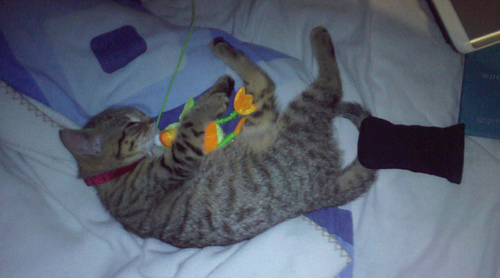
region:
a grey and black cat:
[56, 28, 403, 240]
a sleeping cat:
[47, 39, 424, 240]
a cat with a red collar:
[29, 80, 189, 205]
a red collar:
[64, 143, 156, 201]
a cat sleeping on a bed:
[18, 35, 409, 255]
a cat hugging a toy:
[89, 28, 419, 238]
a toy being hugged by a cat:
[158, 71, 267, 153]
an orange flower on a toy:
[193, 73, 265, 154]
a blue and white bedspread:
[6, 28, 167, 120]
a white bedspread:
[6, 81, 56, 207]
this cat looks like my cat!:
[54, 32, 391, 272]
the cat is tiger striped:
[59, 16, 404, 243]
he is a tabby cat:
[51, 19, 401, 257]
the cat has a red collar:
[54, 15, 423, 262]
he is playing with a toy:
[78, 85, 274, 237]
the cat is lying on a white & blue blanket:
[30, 47, 405, 252]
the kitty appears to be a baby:
[56, 10, 409, 249]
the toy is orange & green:
[147, 49, 284, 161]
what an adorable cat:
[28, 5, 450, 260]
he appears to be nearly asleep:
[47, 12, 415, 263]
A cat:
[123, 43, 317, 275]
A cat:
[127, 106, 226, 174]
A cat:
[185, 84, 268, 220]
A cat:
[141, 132, 265, 237]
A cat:
[187, 58, 254, 141]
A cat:
[198, 179, 308, 271]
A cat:
[179, 136, 295, 255]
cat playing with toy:
[34, 74, 334, 216]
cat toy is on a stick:
[100, 26, 275, 163]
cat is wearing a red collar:
[77, 140, 167, 196]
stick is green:
[170, 20, 194, 114]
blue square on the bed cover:
[84, 23, 154, 70]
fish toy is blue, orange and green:
[159, 98, 266, 150]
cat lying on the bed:
[55, 79, 405, 270]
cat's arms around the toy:
[158, 58, 228, 171]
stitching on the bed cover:
[1, 91, 66, 131]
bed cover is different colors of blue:
[40, 5, 185, 107]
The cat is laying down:
[64, 77, 278, 262]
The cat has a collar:
[29, 108, 164, 222]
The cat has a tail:
[296, 53, 471, 248]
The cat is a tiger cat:
[54, 54, 386, 269]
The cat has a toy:
[138, 82, 259, 177]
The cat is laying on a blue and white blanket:
[30, 48, 460, 224]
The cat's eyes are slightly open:
[104, 66, 169, 160]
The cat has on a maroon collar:
[50, 143, 165, 205]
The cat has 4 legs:
[146, 21, 443, 248]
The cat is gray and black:
[42, 53, 352, 276]